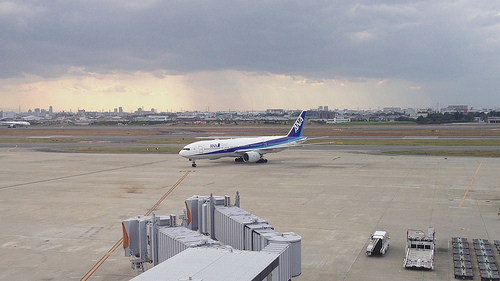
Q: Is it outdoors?
A: Yes, it is outdoors.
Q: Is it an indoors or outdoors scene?
A: It is outdoors.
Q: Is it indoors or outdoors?
A: It is outdoors.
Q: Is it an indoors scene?
A: No, it is outdoors.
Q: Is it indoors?
A: No, it is outdoors.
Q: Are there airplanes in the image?
A: Yes, there is an airplane.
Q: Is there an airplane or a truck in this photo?
A: Yes, there is an airplane.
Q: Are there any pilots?
A: No, there are no pilots.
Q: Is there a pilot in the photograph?
A: No, there are no pilots.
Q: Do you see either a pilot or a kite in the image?
A: No, there are no pilots or kites.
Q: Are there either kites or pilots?
A: No, there are no pilots or kites.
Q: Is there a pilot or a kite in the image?
A: No, there are no pilots or kites.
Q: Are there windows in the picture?
A: Yes, there are windows.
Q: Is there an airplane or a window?
A: Yes, there are windows.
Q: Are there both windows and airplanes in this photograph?
A: Yes, there are both windows and an airplane.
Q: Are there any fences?
A: No, there are no fences.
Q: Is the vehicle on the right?
A: Yes, the vehicle is on the right of the image.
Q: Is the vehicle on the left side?
A: No, the vehicle is on the right of the image.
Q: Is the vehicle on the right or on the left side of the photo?
A: The vehicle is on the right of the image.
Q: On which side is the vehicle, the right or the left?
A: The vehicle is on the right of the image.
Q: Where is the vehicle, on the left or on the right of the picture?
A: The vehicle is on the right of the image.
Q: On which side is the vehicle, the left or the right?
A: The vehicle is on the right of the image.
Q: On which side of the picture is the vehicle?
A: The vehicle is on the right of the image.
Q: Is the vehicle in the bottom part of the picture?
A: Yes, the vehicle is in the bottom of the image.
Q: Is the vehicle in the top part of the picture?
A: No, the vehicle is in the bottom of the image.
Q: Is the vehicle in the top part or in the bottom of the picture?
A: The vehicle is in the bottom of the image.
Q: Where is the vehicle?
A: The vehicle is on the runway.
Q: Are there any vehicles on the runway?
A: Yes, there is a vehicle on the runway.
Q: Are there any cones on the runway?
A: No, there is a vehicle on the runway.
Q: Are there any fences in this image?
A: No, there are no fences.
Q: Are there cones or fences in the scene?
A: No, there are no fences or cones.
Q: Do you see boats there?
A: No, there are no boats.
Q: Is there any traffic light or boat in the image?
A: No, there are no boats or traffic lights.